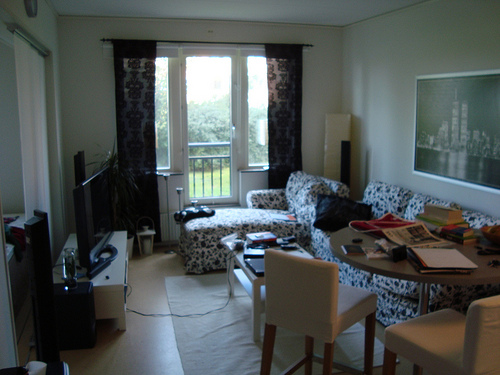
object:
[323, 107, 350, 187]
lamp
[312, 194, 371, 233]
pillow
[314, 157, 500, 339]
sofa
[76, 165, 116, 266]
screen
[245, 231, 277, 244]
book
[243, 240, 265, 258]
book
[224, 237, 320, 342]
table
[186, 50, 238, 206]
door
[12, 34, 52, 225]
curtain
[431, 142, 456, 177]
ground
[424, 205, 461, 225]
books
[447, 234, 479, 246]
books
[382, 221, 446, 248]
books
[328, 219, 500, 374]
table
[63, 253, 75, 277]
vase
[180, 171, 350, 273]
chair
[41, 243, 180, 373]
brown floor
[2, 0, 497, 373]
house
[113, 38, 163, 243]
curtains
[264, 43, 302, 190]
curtains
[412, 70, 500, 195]
framed art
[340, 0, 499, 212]
wall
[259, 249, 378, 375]
chair legs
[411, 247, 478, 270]
books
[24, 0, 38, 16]
round clock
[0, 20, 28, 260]
side window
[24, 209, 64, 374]
speaker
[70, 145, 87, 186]
speaker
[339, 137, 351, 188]
speaker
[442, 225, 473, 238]
books